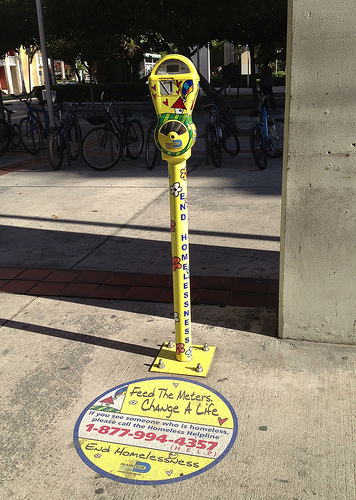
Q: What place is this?
A: It is a city.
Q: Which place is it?
A: It is a city.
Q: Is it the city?
A: Yes, it is the city.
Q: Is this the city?
A: Yes, it is the city.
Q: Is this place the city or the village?
A: It is the city.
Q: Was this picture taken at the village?
A: No, the picture was taken in the city.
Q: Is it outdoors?
A: Yes, it is outdoors.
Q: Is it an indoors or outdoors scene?
A: It is outdoors.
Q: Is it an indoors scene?
A: No, it is outdoors.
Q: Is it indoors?
A: No, it is outdoors.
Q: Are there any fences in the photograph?
A: No, there are no fences.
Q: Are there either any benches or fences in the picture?
A: No, there are no fences or benches.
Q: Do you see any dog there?
A: Yes, there is a dog.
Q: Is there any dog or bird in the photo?
A: Yes, there is a dog.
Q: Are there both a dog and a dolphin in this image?
A: No, there is a dog but no dolphins.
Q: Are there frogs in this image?
A: No, there are no frogs.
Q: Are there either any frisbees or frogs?
A: No, there are no frogs or frisbees.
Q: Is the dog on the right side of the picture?
A: Yes, the dog is on the right of the image.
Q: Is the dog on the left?
A: No, the dog is on the right of the image.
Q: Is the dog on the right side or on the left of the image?
A: The dog is on the right of the image.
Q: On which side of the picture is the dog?
A: The dog is on the right of the image.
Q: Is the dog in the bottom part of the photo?
A: Yes, the dog is in the bottom of the image.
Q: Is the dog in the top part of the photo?
A: No, the dog is in the bottom of the image.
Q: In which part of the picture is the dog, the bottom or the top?
A: The dog is in the bottom of the image.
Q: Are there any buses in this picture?
A: No, there are no buses.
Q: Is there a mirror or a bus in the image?
A: No, there are no buses or mirrors.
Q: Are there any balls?
A: No, there are no balls.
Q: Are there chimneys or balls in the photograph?
A: No, there are no balls or chimneys.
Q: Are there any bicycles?
A: Yes, there is a bicycle.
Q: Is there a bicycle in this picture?
A: Yes, there is a bicycle.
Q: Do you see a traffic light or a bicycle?
A: Yes, there is a bicycle.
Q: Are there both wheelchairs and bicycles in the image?
A: No, there is a bicycle but no wheelchairs.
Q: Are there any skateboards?
A: No, there are no skateboards.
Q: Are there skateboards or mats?
A: No, there are no skateboards or mats.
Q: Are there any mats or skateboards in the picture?
A: No, there are no skateboards or mats.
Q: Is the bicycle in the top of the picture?
A: Yes, the bicycle is in the top of the image.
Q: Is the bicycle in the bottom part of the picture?
A: No, the bicycle is in the top of the image.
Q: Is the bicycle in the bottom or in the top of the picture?
A: The bicycle is in the top of the image.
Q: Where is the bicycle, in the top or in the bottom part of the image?
A: The bicycle is in the top of the image.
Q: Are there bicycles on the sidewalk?
A: Yes, there is a bicycle on the sidewalk.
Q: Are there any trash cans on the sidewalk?
A: No, there is a bicycle on the sidewalk.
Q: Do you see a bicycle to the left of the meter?
A: Yes, there is a bicycle to the left of the meter.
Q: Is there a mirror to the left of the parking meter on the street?
A: No, there is a bicycle to the left of the meter.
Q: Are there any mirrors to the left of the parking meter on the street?
A: No, there is a bicycle to the left of the meter.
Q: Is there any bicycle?
A: Yes, there is a bicycle.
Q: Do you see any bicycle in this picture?
A: Yes, there is a bicycle.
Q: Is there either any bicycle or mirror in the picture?
A: Yes, there is a bicycle.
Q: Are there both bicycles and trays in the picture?
A: No, there is a bicycle but no trays.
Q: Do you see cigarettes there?
A: No, there are no cigarettes.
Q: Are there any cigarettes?
A: No, there are no cigarettes.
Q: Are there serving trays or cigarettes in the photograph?
A: No, there are no cigarettes or serving trays.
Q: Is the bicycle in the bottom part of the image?
A: No, the bicycle is in the top of the image.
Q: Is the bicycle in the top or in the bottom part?
A: The bicycle is in the top of the image.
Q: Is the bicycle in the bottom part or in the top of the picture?
A: The bicycle is in the top of the image.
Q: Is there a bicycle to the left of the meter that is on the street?
A: Yes, there is a bicycle to the left of the parking meter.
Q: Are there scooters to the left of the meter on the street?
A: No, there is a bicycle to the left of the parking meter.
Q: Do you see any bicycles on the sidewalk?
A: Yes, there is a bicycle on the sidewalk.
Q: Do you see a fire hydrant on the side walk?
A: No, there is a bicycle on the side walk.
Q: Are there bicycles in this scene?
A: Yes, there is a bicycle.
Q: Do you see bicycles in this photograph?
A: Yes, there is a bicycle.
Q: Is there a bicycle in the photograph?
A: Yes, there is a bicycle.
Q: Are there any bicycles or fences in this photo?
A: Yes, there is a bicycle.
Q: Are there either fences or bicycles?
A: Yes, there is a bicycle.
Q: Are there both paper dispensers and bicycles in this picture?
A: No, there is a bicycle but no paper dispensers.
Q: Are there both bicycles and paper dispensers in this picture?
A: No, there is a bicycle but no paper dispensers.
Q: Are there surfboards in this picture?
A: No, there are no surfboards.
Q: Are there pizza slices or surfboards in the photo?
A: No, there are no surfboards or pizza slices.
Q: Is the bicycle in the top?
A: Yes, the bicycle is in the top of the image.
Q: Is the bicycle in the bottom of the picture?
A: No, the bicycle is in the top of the image.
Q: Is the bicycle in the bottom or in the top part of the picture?
A: The bicycle is in the top of the image.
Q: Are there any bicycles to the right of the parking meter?
A: Yes, there is a bicycle to the right of the parking meter.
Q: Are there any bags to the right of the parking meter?
A: No, there is a bicycle to the right of the parking meter.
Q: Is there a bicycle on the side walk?
A: Yes, there is a bicycle on the side walk.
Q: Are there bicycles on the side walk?
A: Yes, there is a bicycle on the side walk.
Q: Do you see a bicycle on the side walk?
A: Yes, there is a bicycle on the side walk.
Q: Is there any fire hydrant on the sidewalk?
A: No, there is a bicycle on the sidewalk.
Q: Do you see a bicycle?
A: Yes, there is a bicycle.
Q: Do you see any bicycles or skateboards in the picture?
A: Yes, there is a bicycle.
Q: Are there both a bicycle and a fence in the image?
A: No, there is a bicycle but no fences.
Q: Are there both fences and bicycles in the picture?
A: No, there is a bicycle but no fences.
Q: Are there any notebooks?
A: No, there are no notebooks.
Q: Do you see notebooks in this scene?
A: No, there are no notebooks.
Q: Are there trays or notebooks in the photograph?
A: No, there are no notebooks or trays.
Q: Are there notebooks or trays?
A: No, there are no notebooks or trays.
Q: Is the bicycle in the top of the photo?
A: Yes, the bicycle is in the top of the image.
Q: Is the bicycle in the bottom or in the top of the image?
A: The bicycle is in the top of the image.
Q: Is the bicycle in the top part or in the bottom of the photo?
A: The bicycle is in the top of the image.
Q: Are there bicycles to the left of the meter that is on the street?
A: Yes, there is a bicycle to the left of the meter.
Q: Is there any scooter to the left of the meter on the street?
A: No, there is a bicycle to the left of the parking meter.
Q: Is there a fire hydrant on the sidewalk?
A: No, there is a bicycle on the sidewalk.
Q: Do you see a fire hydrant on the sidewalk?
A: No, there is a bicycle on the sidewalk.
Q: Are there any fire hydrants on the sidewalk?
A: No, there is a bicycle on the sidewalk.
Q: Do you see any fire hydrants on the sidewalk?
A: No, there is a bicycle on the sidewalk.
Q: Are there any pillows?
A: No, there are no pillows.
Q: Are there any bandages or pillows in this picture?
A: No, there are no pillows or bandages.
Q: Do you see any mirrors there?
A: No, there are no mirrors.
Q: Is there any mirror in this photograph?
A: No, there are no mirrors.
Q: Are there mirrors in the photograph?
A: No, there are no mirrors.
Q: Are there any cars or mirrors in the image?
A: No, there are no mirrors or cars.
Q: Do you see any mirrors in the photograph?
A: No, there are no mirrors.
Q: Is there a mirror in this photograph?
A: No, there are no mirrors.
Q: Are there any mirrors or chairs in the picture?
A: No, there are no mirrors or chairs.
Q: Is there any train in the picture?
A: No, there are no trains.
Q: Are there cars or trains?
A: No, there are no trains or cars.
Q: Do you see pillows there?
A: No, there are no pillows.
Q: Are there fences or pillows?
A: No, there are no pillows or fences.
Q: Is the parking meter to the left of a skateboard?
A: No, the parking meter is to the left of a bicycle.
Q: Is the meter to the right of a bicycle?
A: Yes, the meter is to the right of a bicycle.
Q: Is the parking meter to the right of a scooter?
A: No, the parking meter is to the right of a bicycle.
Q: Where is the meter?
A: The meter is on the street.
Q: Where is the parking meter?
A: The meter is on the street.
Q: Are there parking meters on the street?
A: Yes, there is a parking meter on the street.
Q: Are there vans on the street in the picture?
A: No, there is a parking meter on the street.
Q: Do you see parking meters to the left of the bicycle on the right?
A: Yes, there is a parking meter to the left of the bicycle.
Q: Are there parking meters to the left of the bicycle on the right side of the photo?
A: Yes, there is a parking meter to the left of the bicycle.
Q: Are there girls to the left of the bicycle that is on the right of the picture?
A: No, there is a parking meter to the left of the bicycle.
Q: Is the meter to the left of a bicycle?
A: Yes, the meter is to the left of a bicycle.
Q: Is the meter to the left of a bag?
A: No, the meter is to the left of a bicycle.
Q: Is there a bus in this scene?
A: No, there are no buses.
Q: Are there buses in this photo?
A: No, there are no buses.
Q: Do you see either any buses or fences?
A: No, there are no buses or fences.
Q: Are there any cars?
A: No, there are no cars.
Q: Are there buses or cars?
A: No, there are no cars or buses.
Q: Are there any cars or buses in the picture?
A: No, there are no cars or buses.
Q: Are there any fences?
A: No, there are no fences.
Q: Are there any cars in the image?
A: No, there are no cars.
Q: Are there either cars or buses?
A: No, there are no cars or buses.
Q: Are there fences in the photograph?
A: No, there are no fences.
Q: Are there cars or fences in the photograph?
A: No, there are no fences or cars.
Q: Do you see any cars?
A: No, there are no cars.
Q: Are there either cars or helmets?
A: No, there are no cars or helmets.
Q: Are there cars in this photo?
A: No, there are no cars.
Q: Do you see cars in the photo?
A: No, there are no cars.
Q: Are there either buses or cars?
A: No, there are no cars or buses.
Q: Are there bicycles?
A: Yes, there is a bicycle.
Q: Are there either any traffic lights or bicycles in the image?
A: Yes, there is a bicycle.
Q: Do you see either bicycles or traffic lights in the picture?
A: Yes, there is a bicycle.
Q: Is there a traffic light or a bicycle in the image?
A: Yes, there is a bicycle.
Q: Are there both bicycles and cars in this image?
A: No, there is a bicycle but no cars.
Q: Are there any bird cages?
A: No, there are no bird cages.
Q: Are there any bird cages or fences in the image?
A: No, there are no bird cages or fences.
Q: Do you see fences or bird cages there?
A: No, there are no bird cages or fences.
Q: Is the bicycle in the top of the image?
A: Yes, the bicycle is in the top of the image.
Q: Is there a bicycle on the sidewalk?
A: Yes, there is a bicycle on the sidewalk.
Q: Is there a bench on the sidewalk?
A: No, there is a bicycle on the sidewalk.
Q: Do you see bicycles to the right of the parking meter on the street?
A: Yes, there is a bicycle to the right of the parking meter.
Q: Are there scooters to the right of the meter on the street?
A: No, there is a bicycle to the right of the meter.